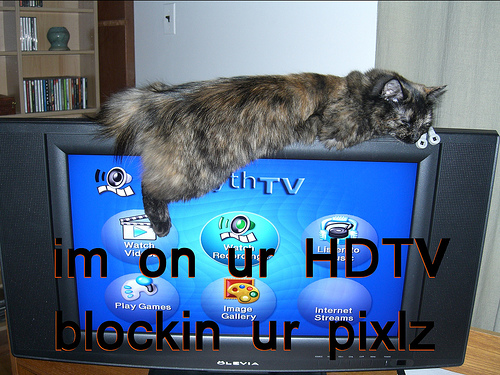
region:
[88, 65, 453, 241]
cat laying on tv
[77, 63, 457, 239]
cat relaxing on television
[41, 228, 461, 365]
words on bottom of photo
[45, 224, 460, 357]
black words on photo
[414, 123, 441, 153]
white earbuds under cat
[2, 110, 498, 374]
black television under cat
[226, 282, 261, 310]
paint palette icon on television screen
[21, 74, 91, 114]
row of dvds on bottom shelf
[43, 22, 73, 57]
green ceramic knick knack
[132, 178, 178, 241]
cat foot hanging down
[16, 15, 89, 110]
Movies organized on a shelf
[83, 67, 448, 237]
Cat laying on top of a tv screen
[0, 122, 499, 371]
television with two spearkers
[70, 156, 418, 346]
menu on a television screen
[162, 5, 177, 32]
a light switch on the wall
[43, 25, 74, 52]
pottery on a shelf in a bookcase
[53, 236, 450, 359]
text on picture indicating a meme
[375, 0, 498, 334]
Off white curtains over a window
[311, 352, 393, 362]
buttons on a television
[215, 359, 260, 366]
name brand of manufacturer on front of television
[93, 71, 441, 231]
cat laying on the tv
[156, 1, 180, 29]
white light switch on the wall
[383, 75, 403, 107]
the cat's right ear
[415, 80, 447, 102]
the cat's left ear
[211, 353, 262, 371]
name brand on television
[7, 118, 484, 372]
television on the floor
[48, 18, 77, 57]
vase on the bookcase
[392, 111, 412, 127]
right eye on the cat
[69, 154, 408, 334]
screen on the television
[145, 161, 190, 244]
the cat's right leg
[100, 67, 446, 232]
a cat sleeping on top of a TV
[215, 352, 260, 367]
a company brand name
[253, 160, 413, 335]
the digital display on the screen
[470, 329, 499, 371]
a hard wood flooring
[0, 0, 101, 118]
a wooden book shelf against the wall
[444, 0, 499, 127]
window curtains against the wall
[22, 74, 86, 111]
a stack of CD covers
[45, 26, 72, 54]
arts and craft ceramic bowl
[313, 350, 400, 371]
the television's control panel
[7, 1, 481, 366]
a cat laying on a tv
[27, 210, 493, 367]
humorous text describing the image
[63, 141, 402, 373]
the screen of a smart tv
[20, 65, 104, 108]
a shelf filled with DVDs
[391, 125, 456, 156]
a pair of head phones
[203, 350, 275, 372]
the olevia logo on a tv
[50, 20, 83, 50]
a vase on a shelf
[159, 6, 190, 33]
a wall mounted light switch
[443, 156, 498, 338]
a speaker built in to a television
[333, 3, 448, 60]
a curtain covering a window